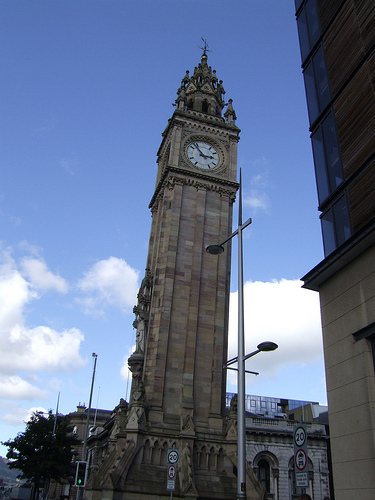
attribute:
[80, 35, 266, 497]
clock tower — large, leaning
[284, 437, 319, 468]
sign — bus stop, red, white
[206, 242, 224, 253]
light — green, round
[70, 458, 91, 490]
traffic light — black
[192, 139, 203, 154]
hand — big, black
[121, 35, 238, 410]
tower — very tall, clock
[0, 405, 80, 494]
tree — green, leafy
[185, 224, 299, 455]
streetlight — silver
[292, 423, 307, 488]
sign — rectangle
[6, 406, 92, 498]
tree — tall , green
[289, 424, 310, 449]
sign — round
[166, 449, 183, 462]
sign — round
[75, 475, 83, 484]
green light — lit